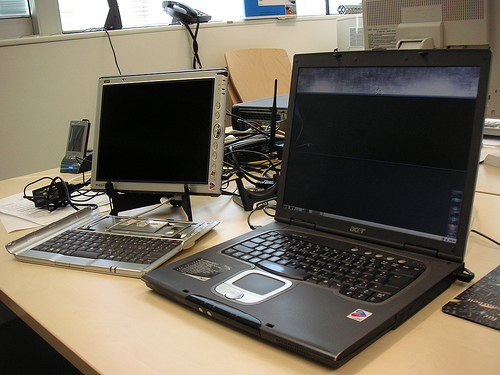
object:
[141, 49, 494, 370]
laptop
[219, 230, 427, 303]
keyboard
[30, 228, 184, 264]
keyboard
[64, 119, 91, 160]
cellphone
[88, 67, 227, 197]
monitor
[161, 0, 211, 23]
handset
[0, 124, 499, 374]
desk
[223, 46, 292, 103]
chair back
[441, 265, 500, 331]
mouse pad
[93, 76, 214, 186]
screen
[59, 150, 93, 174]
charger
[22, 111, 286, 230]
cords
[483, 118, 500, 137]
keyboard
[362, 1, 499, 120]
monitor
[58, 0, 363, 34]
window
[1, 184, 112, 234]
paper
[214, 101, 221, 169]
buttons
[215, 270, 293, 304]
mouse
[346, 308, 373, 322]
logo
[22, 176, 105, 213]
power cord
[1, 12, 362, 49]
window sill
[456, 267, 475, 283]
power cord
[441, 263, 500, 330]
design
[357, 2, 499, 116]
back